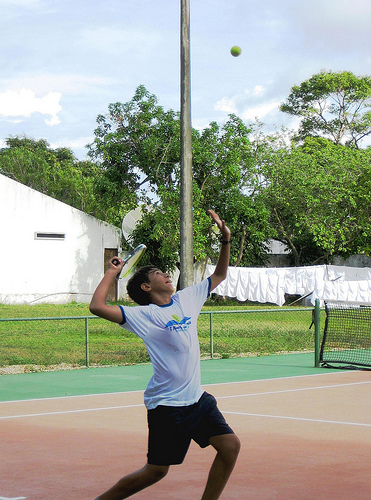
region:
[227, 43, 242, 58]
a green tennis ball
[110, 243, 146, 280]
a green and white tennis racket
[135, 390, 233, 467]
a man's black shorts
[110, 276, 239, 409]
a man's short sleeve shirt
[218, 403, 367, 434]
a long white line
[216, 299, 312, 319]
a long green pole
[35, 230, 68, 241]
a long window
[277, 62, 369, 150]
part of a large tree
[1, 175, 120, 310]
part of a white building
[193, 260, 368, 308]
white clothes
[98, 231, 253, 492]
The boy is playing tennis.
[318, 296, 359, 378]
Net on the court.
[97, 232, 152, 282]
The boy is holding a tennis racket.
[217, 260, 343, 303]
Sheets on the clothes line.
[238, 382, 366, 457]
White lines on the court.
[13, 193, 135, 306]
Side of a house.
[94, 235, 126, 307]
A wooden door on the house.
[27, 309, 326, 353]
A fence surrounding the court.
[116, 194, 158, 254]
A satellite behind the tree.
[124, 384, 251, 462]
The boy is wearing blue shorts.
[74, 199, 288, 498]
young man swinging tennis racket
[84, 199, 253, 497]
young man wearing black watch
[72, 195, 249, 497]
young man wearing white shirt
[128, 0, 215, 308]
electrical pole in background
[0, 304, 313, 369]
chain link fence lining tennis court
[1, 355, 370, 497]
green and brown tennis court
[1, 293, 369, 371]
bright green grass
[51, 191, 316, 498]
young man in mid swing with tennis racket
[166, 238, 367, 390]
clothes hanging on clothes line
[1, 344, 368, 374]
dirt on border of tennis court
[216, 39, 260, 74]
A tennis ball in the air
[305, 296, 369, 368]
A tennis net on a court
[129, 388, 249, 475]
A boy wearing dark shorts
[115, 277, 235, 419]
A boy wearing a white shirt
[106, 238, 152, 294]
A boy holding a tennis racket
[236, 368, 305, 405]
Lines painted on a tennis court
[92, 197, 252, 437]
A boy swinging a tennis racket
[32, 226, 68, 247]
A window on the side of a white building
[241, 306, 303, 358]
A metal fence on the side of a tennis court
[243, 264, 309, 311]
White sheets hanging on a clothes line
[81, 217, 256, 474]
a kid playing tennis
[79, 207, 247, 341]
this kid is swinging upward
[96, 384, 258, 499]
his legs are bent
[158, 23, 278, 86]
the ball is in the air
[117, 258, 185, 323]
this player is looking upward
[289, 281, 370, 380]
a tennis net on the court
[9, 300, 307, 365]
a fence along the court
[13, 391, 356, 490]
the court is red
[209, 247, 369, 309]
the tent is white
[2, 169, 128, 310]
the building is white